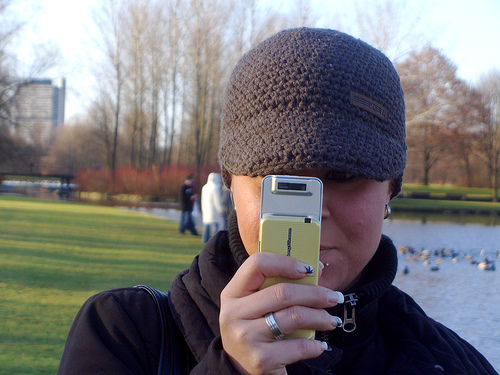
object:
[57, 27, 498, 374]
woman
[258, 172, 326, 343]
phone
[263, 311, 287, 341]
ring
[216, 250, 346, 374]
hand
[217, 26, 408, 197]
cap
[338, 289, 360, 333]
zipper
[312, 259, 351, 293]
chin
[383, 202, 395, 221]
earring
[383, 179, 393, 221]
ear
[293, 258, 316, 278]
nails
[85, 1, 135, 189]
trees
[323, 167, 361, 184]
eye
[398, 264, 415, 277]
ducks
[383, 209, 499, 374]
pond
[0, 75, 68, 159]
building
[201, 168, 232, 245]
person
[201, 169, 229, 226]
hoodie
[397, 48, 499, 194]
trees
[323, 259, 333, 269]
lip piercing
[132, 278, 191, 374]
strap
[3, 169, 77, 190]
bridge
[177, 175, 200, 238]
man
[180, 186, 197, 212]
shirt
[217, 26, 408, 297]
head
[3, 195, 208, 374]
grass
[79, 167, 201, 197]
bushes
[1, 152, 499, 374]
park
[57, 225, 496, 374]
jacket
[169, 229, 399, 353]
collar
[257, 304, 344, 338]
finger